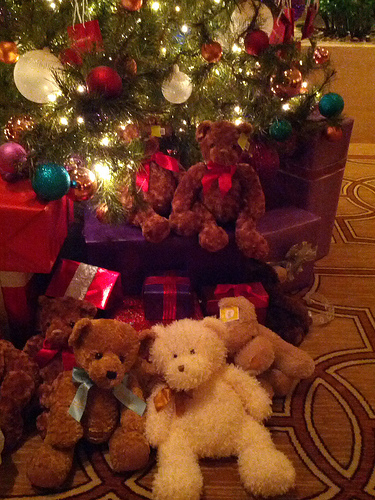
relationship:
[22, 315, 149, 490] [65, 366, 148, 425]
teddy bear with ribbon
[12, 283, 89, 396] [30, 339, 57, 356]
teddy bear with ribbon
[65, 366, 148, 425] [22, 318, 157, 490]
ribbon on teddy bear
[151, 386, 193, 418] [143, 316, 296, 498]
ribbon on bear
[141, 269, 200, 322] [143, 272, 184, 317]
present with ribbon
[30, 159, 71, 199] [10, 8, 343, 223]
ornament on tree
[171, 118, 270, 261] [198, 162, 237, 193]
bear with a ribbon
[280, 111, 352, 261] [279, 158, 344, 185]
present with ribbon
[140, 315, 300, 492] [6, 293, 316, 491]
bear in a pile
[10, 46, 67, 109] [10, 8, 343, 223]
ornament on a tree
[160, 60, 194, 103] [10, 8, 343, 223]
ornament on a tree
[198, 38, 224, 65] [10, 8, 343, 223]
ornament on a tree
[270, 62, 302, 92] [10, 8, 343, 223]
ornament on a tree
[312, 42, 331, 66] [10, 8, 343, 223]
ornament on a tree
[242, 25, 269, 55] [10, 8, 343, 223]
ornament on a tree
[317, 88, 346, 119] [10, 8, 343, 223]
ornament on a tree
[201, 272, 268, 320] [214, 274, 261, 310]
gift box has bow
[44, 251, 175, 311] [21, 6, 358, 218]
box by tree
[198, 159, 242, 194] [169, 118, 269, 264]
ribbon on teddy bear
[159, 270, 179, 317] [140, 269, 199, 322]
lace on box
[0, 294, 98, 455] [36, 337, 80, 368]
teddy bear wearing ribbon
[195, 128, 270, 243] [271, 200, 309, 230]
teddy bear on chair